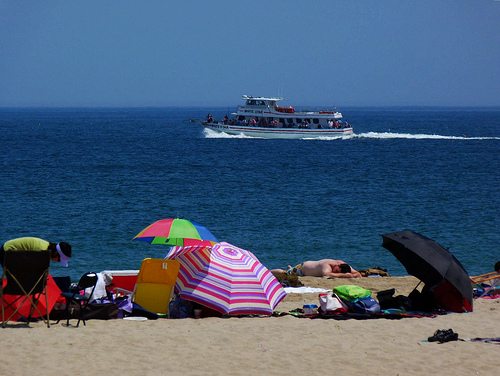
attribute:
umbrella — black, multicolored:
[384, 222, 468, 302]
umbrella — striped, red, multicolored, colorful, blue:
[174, 229, 268, 298]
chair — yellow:
[142, 260, 193, 321]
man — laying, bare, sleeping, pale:
[301, 250, 358, 286]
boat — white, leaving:
[192, 90, 375, 161]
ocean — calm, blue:
[152, 138, 247, 206]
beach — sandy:
[215, 304, 286, 374]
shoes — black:
[424, 325, 463, 349]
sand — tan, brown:
[308, 337, 340, 359]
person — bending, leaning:
[11, 222, 82, 265]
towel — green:
[299, 283, 331, 300]